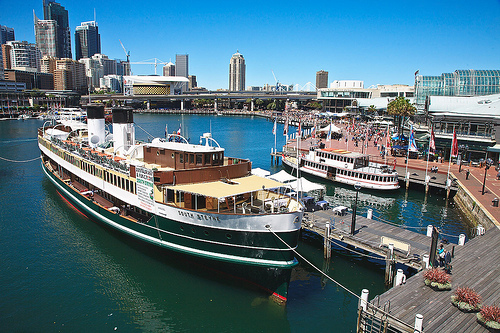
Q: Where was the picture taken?
A: A dock.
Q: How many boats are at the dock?
A: Two.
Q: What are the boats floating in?
A: Water.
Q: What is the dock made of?
A: Wood.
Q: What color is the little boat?
A: White.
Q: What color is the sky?
A: Blue.